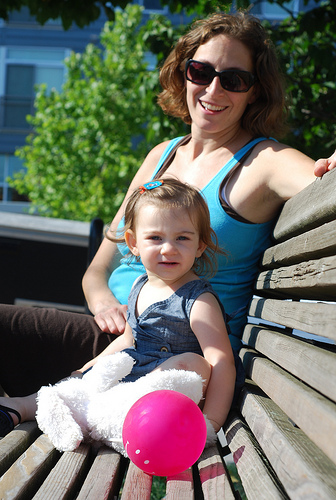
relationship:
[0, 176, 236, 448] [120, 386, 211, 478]
baby girl has balloon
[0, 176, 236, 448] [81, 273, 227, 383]
baby girl wearing dress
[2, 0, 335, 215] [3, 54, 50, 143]
building has window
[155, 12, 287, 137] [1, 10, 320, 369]
head of a woman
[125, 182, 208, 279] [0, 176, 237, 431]
head of a baby girl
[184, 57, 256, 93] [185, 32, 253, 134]
glasses on face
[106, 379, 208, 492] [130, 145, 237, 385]
balloon near toddler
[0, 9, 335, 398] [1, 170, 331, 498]
woman and toddler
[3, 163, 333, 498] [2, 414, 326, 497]
bench has part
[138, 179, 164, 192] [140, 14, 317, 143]
barrette in hair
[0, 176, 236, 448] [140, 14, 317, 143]
baby girl has hair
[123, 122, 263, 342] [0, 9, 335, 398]
top on woman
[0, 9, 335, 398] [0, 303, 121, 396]
woman wearing pants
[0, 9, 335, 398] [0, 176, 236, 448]
woman sitting with baby girl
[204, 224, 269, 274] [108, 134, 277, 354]
woman wearing tank top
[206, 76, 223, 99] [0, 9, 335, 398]
nose of woman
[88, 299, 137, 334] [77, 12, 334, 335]
hand of a woman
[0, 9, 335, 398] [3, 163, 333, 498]
woman sits on bench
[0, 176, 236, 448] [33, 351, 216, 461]
baby girl has animal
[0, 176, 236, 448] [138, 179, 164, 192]
baby girl wearing barrette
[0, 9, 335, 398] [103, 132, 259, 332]
woman wearing tank top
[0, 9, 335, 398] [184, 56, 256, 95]
woman wearing glasses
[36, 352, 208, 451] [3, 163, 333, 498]
animal on bench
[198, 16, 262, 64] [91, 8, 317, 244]
forehead on woman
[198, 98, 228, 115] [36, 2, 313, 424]
mouth on woman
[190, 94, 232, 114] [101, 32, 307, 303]
teeth on woman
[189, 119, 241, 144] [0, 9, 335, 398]
neck on woman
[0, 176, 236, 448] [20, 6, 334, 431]
baby girl sitting with woman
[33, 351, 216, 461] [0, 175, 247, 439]
animal next to toddler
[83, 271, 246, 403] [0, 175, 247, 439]
dress on toddler